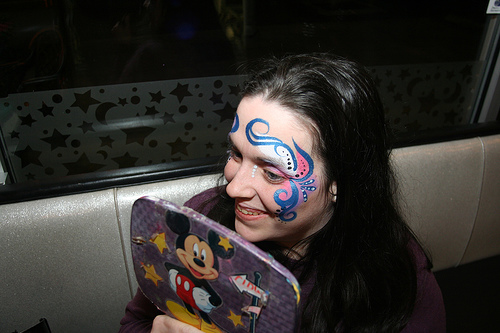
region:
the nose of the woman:
[222, 155, 256, 199]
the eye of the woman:
[259, 158, 289, 183]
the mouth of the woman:
[231, 196, 271, 223]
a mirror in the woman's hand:
[125, 194, 309, 331]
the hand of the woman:
[146, 310, 208, 332]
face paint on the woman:
[242, 115, 325, 227]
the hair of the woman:
[238, 49, 436, 329]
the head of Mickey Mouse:
[162, 206, 237, 281]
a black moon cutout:
[93, 93, 119, 128]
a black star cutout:
[68, 86, 102, 117]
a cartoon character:
[159, 218, 231, 331]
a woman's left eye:
[258, 163, 286, 183]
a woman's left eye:
[227, 143, 244, 160]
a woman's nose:
[225, 176, 250, 199]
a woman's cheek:
[255, 185, 296, 218]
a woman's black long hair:
[246, 52, 415, 324]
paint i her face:
[236, 115, 315, 235]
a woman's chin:
[231, 220, 261, 242]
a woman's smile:
[228, 200, 270, 220]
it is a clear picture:
[1, 0, 497, 331]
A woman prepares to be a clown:
[210, 108, 319, 243]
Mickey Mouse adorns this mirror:
[124, 196, 266, 331]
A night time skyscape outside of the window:
[1, 81, 496, 172]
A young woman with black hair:
[216, 45, 441, 331]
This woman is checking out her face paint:
[122, 51, 450, 331]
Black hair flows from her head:
[103, 56, 448, 327]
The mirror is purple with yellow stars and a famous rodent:
[119, 196, 291, 331]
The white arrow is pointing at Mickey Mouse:
[115, 196, 296, 331]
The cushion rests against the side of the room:
[2, 133, 499, 330]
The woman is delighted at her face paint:
[122, 46, 432, 331]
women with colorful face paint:
[70, 36, 475, 331]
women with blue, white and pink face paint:
[114, 65, 429, 329]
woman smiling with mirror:
[106, 38, 448, 331]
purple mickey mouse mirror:
[135, 192, 298, 332]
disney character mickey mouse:
[145, 201, 245, 331]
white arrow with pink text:
[226, 265, 271, 306]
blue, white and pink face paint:
[239, 107, 329, 229]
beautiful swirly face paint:
[241, 108, 339, 232]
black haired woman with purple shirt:
[69, 51, 444, 327]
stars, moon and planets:
[3, 77, 280, 174]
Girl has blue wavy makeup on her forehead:
[244, 114, 288, 149]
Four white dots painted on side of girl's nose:
[248, 161, 258, 181]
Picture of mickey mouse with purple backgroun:
[159, 211, 229, 331]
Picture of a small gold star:
[137, 259, 163, 289]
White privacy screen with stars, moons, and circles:
[8, 86, 218, 154]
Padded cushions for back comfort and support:
[401, 148, 498, 267]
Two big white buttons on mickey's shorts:
[173, 274, 190, 291]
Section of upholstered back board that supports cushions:
[8, 160, 212, 195]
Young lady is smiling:
[227, 198, 274, 220]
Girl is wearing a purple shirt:
[115, 187, 452, 332]